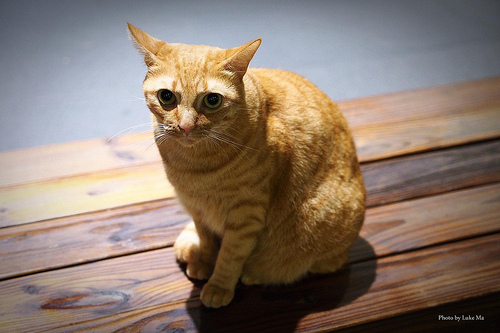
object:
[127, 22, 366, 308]
cat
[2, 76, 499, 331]
bench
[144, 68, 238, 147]
face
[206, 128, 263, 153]
whisker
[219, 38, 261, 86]
ear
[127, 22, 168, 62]
ear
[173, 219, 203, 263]
tail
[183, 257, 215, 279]
paw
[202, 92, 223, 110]
eye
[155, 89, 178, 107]
eye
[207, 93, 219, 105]
pupil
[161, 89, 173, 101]
pupil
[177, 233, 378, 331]
shadow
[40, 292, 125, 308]
knot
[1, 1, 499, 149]
wall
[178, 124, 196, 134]
nose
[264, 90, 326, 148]
fur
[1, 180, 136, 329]
wood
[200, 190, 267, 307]
limb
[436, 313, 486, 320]
writing